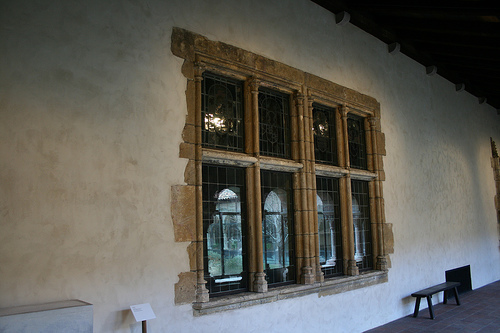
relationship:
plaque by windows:
[127, 299, 159, 326] [174, 27, 389, 302]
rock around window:
[170, 27, 393, 314] [159, 30, 424, 311]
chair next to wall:
[408, 278, 465, 323] [391, 75, 498, 316]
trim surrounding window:
[189, 51, 389, 313] [198, 70, 246, 152]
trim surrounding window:
[189, 51, 389, 313] [201, 159, 251, 296]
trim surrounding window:
[189, 51, 389, 313] [256, 85, 295, 158]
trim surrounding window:
[189, 51, 389, 313] [259, 168, 301, 287]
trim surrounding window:
[189, 51, 389, 313] [315, 173, 344, 278]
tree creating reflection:
[265, 191, 287, 261] [261, 199, 296, 272]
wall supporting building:
[66, 0, 470, 332] [2, 1, 483, 329]